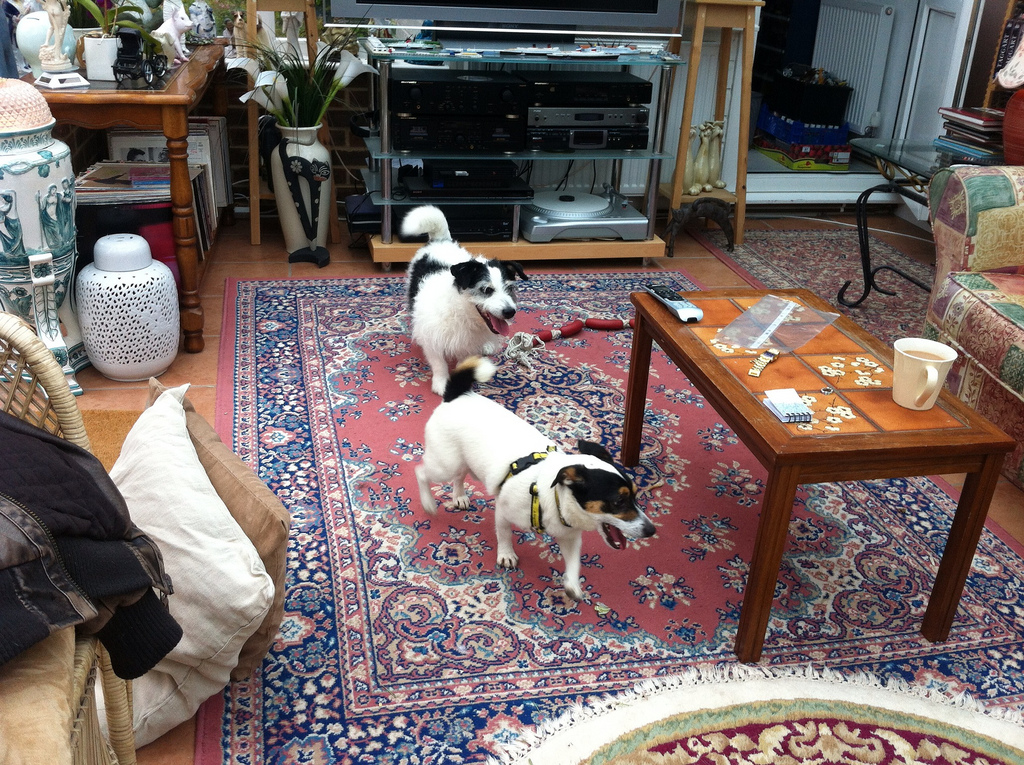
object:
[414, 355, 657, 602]
dog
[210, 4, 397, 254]
plant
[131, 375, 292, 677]
pillow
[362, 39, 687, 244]
stand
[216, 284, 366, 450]
rug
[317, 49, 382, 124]
flowers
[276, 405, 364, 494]
rug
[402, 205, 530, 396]
dog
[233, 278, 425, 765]
rug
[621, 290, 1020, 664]
coffee table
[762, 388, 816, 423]
notepad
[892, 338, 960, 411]
coffee mug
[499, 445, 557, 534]
harness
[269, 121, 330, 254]
vase